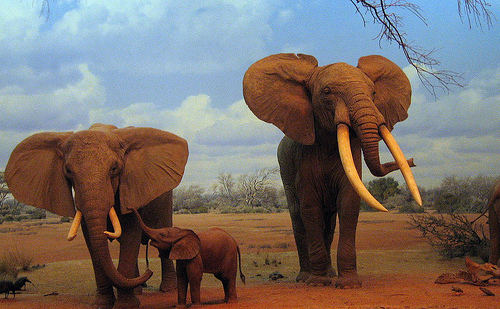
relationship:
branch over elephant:
[350, 0, 470, 103] [242, 52, 425, 291]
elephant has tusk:
[4, 123, 190, 307] [67, 206, 123, 240]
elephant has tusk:
[242, 52, 425, 291] [336, 124, 389, 213]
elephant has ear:
[242, 52, 425, 291] [243, 52, 319, 146]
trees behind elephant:
[362, 176, 498, 214] [242, 52, 425, 291]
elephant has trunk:
[242, 52, 425, 291] [350, 109, 418, 178]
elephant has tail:
[125, 206, 248, 308] [237, 247, 250, 287]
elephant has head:
[242, 52, 425, 291] [244, 52, 415, 145]